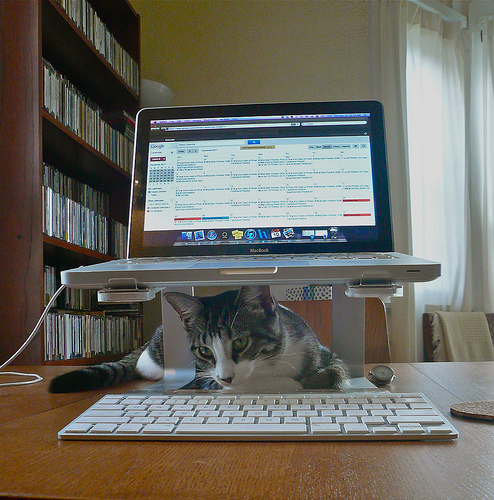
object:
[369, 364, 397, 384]
face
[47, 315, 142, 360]
books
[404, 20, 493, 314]
white curtain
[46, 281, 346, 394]
cat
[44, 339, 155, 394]
tail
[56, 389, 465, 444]
keyboard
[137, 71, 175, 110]
lamp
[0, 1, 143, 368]
wooden shelf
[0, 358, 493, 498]
desk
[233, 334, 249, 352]
eye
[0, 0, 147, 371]
bookshelf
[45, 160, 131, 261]
books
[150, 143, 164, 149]
google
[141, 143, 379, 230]
calendar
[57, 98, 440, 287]
laptop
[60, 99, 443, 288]
computer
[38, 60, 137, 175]
books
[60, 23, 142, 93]
books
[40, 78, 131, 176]
shelf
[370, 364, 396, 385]
watch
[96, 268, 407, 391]
stand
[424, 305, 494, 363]
blanket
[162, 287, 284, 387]
face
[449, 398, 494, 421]
coaster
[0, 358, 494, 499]
table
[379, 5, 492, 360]
windows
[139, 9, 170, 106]
corner